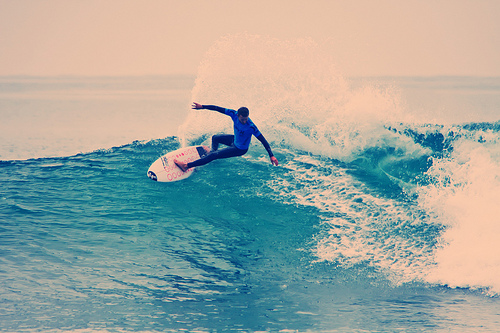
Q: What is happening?
A: A man riding a surfboard.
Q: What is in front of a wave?
A: White foam.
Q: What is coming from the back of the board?
A: White ocean spray.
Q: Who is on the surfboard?
A: A man.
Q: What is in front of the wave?
A: White ocean foam.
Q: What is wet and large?
A: Ocean.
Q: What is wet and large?
A: Ocean.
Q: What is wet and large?
A: Ocean.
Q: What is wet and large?
A: Ocean.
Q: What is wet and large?
A: Ocean.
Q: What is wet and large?
A: Ocean.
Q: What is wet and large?
A: Ocean.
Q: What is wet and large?
A: Ocean.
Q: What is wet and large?
A: Ocean.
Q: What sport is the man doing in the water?
A: Surfing.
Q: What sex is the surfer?
A: Male.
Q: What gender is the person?
A: Male.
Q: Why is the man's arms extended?
A: Balance.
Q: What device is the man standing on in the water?
A: Surfboard.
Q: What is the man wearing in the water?
A: Wet suit.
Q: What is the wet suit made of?
A: Neoprene.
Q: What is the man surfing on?
A: Water.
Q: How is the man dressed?
A: In a wetsuit.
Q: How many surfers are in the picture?
A: One.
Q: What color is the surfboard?
A: White.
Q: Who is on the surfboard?
A: The man.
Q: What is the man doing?
A: Surfing.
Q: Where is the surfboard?
A: In the water.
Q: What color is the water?
A: Blue.